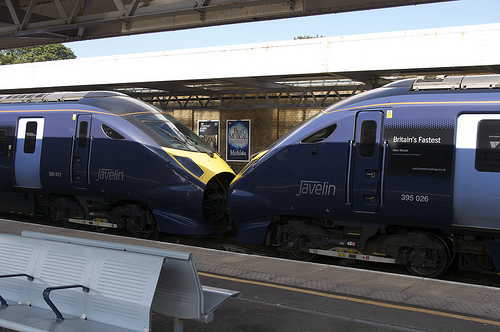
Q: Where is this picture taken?
A: At a train station.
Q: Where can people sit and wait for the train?
A: On the bench.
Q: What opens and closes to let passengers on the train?
A: The doors.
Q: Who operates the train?
A: The conductor.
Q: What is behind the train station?
A: Trees.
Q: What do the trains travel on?
A: Tracks.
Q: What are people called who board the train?
A: Passengers.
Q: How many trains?
A: 2.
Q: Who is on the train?
A: People.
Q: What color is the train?
A: Blue.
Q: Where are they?
A: Station.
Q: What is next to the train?
A: Benches.